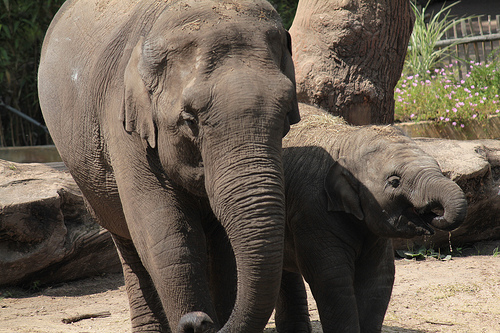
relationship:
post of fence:
[484, 16, 496, 87] [406, 14, 498, 82]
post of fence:
[474, 15, 487, 78] [406, 14, 498, 82]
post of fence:
[458, 14, 472, 82] [406, 14, 498, 82]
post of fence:
[447, 18, 466, 95] [406, 14, 498, 82]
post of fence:
[434, 17, 454, 82] [406, 14, 498, 82]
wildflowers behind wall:
[398, 70, 490, 120] [376, 135, 496, 246]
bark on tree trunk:
[368, 38, 391, 65] [286, 0, 415, 125]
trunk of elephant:
[412, 172, 467, 233] [278, 132, 468, 325]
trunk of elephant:
[181, 140, 302, 330] [33, 1, 303, 330]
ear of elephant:
[318, 153, 378, 233] [278, 132, 468, 325]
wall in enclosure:
[2, 134, 498, 280] [2, 2, 498, 328]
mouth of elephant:
[389, 194, 443, 244] [278, 132, 468, 325]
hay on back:
[306, 111, 333, 123] [284, 120, 378, 141]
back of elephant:
[284, 120, 378, 141] [270, 116, 463, 331]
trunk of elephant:
[412, 172, 462, 232] [283, 120, 473, 331]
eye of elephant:
[386, 175, 400, 189] [278, 132, 468, 325]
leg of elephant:
[296, 252, 360, 331] [278, 132, 468, 325]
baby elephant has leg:
[262, 134, 469, 333] [351, 244, 396, 329]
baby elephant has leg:
[262, 134, 469, 333] [272, 236, 312, 331]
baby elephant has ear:
[262, 134, 469, 333] [319, 159, 369, 229]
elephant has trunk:
[33, 1, 303, 330] [173, 126, 289, 330]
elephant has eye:
[33, 1, 303, 330] [175, 106, 199, 133]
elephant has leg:
[33, 1, 303, 330] [111, 159, 223, 331]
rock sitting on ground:
[4, 149, 121, 291] [7, 276, 140, 330]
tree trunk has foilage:
[286, 3, 423, 125] [404, 0, 458, 87]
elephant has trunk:
[33, 1, 303, 330] [177, 135, 296, 329]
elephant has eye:
[33, 1, 303, 330] [180, 105, 201, 140]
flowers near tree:
[416, 70, 476, 121] [418, 22, 439, 62]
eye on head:
[276, 104, 313, 134] [132, 4, 326, 178]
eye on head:
[380, 160, 408, 192] [327, 123, 440, 238]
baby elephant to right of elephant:
[262, 134, 469, 333] [81, 45, 299, 293]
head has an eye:
[152, 21, 300, 241] [184, 114, 199, 133]